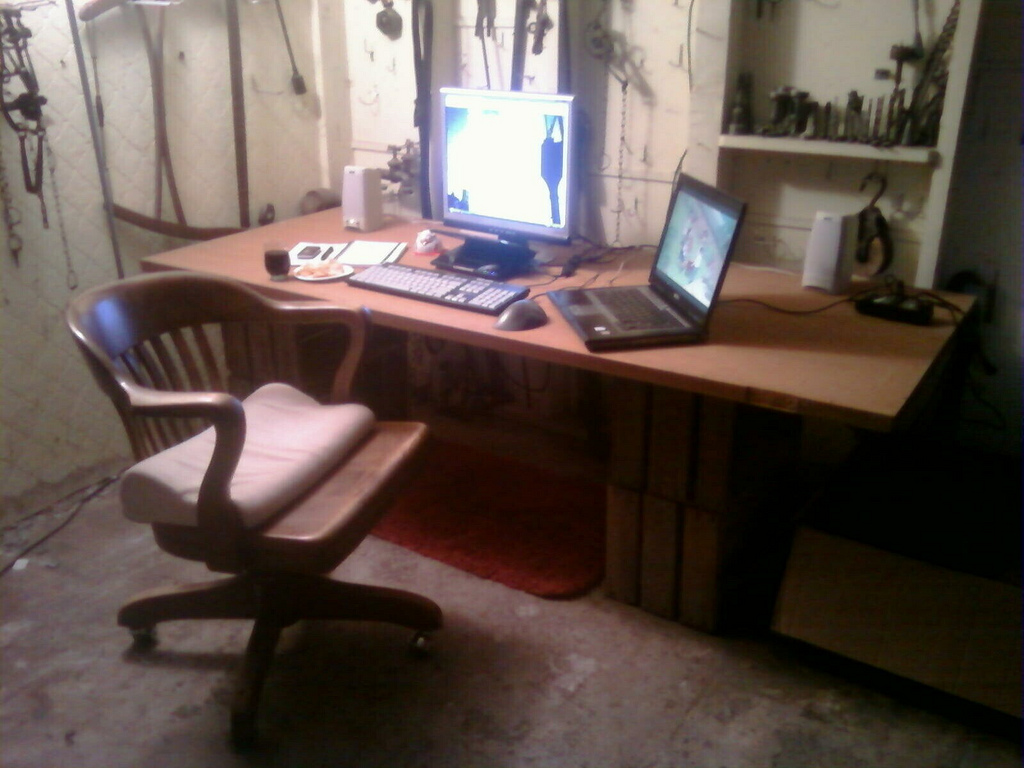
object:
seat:
[120, 380, 377, 530]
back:
[69, 273, 266, 403]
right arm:
[118, 382, 253, 521]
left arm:
[246, 284, 370, 396]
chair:
[60, 258, 452, 742]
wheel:
[131, 629, 159, 651]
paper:
[287, 237, 411, 267]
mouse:
[495, 297, 549, 331]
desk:
[131, 194, 986, 636]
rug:
[321, 421, 614, 602]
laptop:
[545, 171, 752, 350]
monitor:
[417, 87, 576, 247]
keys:
[356, 266, 466, 298]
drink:
[265, 250, 292, 275]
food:
[296, 260, 343, 278]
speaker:
[340, 167, 386, 232]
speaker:
[800, 211, 858, 293]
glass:
[263, 250, 291, 280]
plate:
[291, 259, 352, 289]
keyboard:
[350, 262, 533, 313]